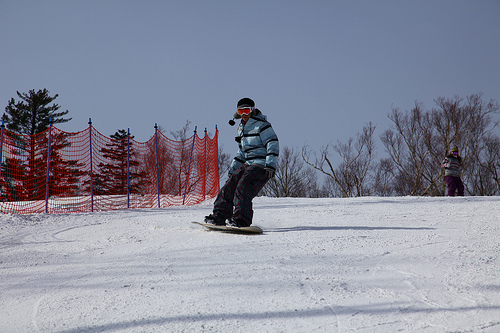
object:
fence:
[0, 117, 220, 213]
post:
[126, 128, 130, 208]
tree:
[0, 89, 86, 201]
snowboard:
[191, 221, 264, 234]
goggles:
[237, 106, 252, 115]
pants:
[204, 165, 269, 227]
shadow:
[261, 225, 435, 232]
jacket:
[228, 113, 280, 178]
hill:
[0, 193, 500, 333]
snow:
[0, 194, 500, 333]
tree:
[377, 91, 500, 197]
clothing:
[203, 108, 279, 226]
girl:
[204, 96, 279, 228]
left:
[0, 0, 105, 333]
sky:
[0, 0, 500, 191]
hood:
[253, 114, 267, 122]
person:
[441, 146, 464, 196]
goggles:
[452, 152, 458, 155]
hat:
[228, 98, 256, 126]